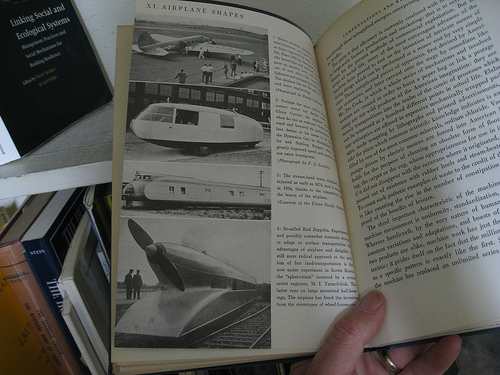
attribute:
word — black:
[312, 202, 323, 207]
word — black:
[375, 11, 392, 24]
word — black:
[403, 51, 425, 67]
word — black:
[281, 98, 295, 106]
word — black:
[302, 95, 312, 102]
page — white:
[111, 0, 371, 362]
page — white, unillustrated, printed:
[314, 0, 500, 346]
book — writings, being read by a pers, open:
[107, 1, 500, 375]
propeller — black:
[128, 219, 186, 292]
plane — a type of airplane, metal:
[116, 218, 260, 348]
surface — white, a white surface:
[0, 2, 134, 197]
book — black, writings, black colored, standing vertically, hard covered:
[20, 185, 87, 373]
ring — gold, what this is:
[379, 348, 400, 374]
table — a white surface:
[212, 1, 357, 46]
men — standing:
[132, 268, 140, 298]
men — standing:
[126, 268, 133, 301]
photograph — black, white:
[113, 217, 272, 350]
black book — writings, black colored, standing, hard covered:
[0, 3, 114, 165]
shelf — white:
[0, 84, 114, 201]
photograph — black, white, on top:
[127, 11, 270, 89]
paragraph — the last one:
[363, 181, 499, 289]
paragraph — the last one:
[275, 226, 359, 307]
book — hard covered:
[2, 191, 86, 370]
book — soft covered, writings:
[61, 212, 110, 372]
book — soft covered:
[60, 293, 107, 374]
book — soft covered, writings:
[82, 185, 109, 265]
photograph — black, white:
[123, 81, 270, 167]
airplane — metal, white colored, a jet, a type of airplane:
[132, 31, 253, 60]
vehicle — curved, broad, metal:
[130, 102, 264, 155]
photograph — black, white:
[119, 159, 271, 220]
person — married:
[289, 290, 461, 375]